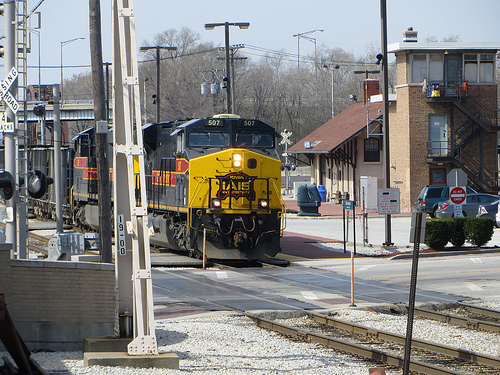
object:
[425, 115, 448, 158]
door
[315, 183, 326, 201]
container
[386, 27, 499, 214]
building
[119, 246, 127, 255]
number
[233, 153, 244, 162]
light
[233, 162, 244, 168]
light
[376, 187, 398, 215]
sign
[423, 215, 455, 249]
bushes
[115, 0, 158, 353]
pole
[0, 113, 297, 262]
train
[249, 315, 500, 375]
tracks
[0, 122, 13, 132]
sign